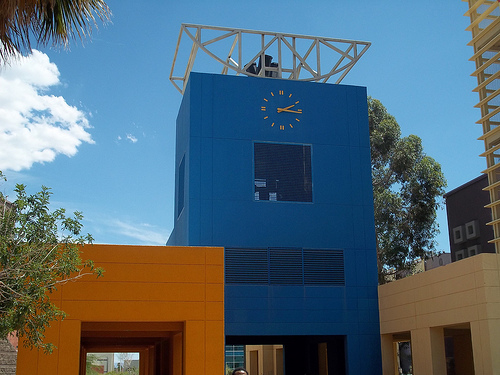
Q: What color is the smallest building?
A: Tan.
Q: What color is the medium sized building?
A: Orange.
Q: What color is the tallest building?
A: Blue.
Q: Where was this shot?
A: Parking lot.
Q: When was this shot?
A: Daytime.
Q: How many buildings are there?
A: 3.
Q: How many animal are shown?
A: 0.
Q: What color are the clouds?
A: White.